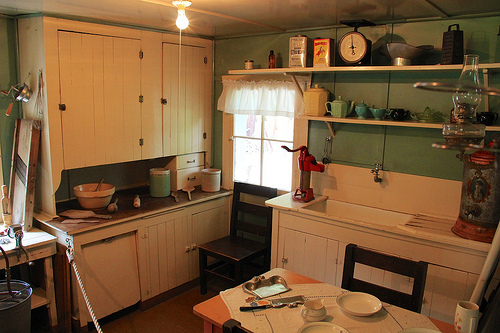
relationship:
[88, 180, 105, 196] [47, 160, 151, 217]
spoon in bowl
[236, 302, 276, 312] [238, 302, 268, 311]
knife with handle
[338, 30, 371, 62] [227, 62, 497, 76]
clock on shelf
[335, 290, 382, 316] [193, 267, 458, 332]
plate on table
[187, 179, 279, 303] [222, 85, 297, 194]
chair near window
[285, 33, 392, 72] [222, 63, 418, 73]
items are on top shelf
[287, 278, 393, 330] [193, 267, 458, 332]
bowls on table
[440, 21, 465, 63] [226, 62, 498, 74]
cheese grater on shelf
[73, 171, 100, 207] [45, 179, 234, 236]
bowl on counter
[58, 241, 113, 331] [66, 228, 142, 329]
rope attached to cabinet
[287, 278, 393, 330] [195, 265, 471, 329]
bowls on table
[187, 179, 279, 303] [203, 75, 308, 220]
chair by window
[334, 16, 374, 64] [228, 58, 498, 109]
scale on shelf